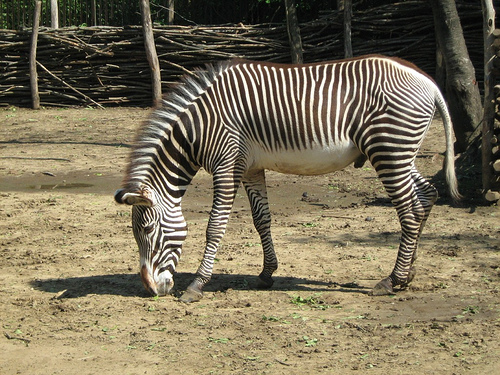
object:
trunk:
[435, 0, 500, 200]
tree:
[139, 2, 164, 104]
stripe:
[366, 144, 418, 165]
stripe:
[372, 159, 417, 173]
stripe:
[386, 180, 412, 192]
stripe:
[285, 67, 309, 147]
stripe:
[321, 60, 331, 146]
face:
[130, 205, 188, 283]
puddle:
[0, 168, 126, 193]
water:
[31, 181, 93, 190]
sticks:
[0, 0, 500, 207]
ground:
[0, 103, 499, 375]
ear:
[120, 193, 153, 208]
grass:
[290, 292, 335, 310]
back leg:
[365, 143, 424, 281]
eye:
[142, 221, 155, 234]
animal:
[114, 53, 462, 299]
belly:
[246, 139, 360, 177]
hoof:
[367, 271, 409, 297]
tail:
[433, 88, 466, 205]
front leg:
[194, 166, 244, 286]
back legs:
[405, 162, 438, 261]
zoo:
[0, 0, 500, 375]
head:
[113, 185, 189, 298]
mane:
[117, 59, 234, 192]